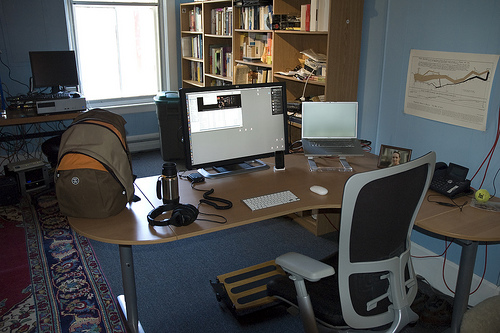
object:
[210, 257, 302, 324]
foot rest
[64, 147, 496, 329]
desk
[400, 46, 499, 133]
chart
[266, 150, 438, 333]
office chair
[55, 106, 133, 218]
backpack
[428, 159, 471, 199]
office phone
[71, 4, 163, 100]
window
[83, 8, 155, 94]
sunlight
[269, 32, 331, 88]
bookshelf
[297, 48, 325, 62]
papers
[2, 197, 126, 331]
carpet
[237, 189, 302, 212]
keyboard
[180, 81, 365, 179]
two monitors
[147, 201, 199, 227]
headphones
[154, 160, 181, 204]
thermos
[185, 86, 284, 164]
computer screen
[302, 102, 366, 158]
laptop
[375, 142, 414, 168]
picture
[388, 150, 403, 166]
lady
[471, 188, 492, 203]
tennis ball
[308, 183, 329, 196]
mouse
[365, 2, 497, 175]
wall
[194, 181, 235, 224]
wires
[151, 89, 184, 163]
garbage can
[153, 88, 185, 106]
green lid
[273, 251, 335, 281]
arm rest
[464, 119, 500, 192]
electric cords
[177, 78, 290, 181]
computer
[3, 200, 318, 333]
floor